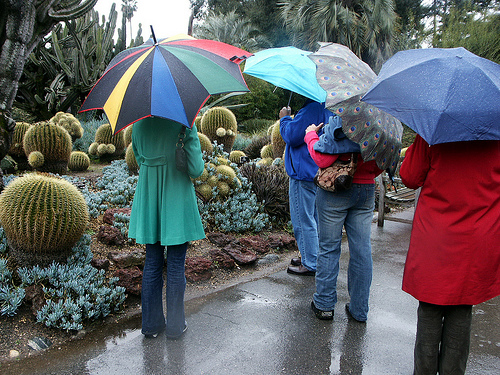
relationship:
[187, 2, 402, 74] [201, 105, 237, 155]
trees amongst cactus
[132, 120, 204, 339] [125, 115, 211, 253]
person wearing coat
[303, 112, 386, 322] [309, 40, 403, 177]
woman holding umbrella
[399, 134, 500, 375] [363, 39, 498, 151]
person holding umbrella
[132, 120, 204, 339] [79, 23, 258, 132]
person holding umbrella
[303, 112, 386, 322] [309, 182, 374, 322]
woman wearing jeans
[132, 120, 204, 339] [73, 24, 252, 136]
person holding umbrella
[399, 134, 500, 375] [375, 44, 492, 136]
person holding blue umbrella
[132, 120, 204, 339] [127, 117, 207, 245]
person wearing coat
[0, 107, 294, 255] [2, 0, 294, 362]
cactus in garden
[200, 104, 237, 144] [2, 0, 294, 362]
cactus in garden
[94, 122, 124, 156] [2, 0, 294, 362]
cactus in garden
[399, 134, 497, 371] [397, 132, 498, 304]
person wearing coat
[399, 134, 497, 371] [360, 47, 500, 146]
person holding blue umbrella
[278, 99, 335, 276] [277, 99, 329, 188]
man wearing coat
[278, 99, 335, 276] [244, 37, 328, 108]
man holding umbrella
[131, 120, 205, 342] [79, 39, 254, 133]
person holding umbrella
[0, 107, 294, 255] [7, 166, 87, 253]
cactus has needles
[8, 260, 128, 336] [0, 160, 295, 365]
plants are covering ground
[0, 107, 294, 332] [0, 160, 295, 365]
plants are covering ground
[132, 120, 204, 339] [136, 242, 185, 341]
person wearing jeans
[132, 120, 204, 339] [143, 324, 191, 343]
person wearing shoes